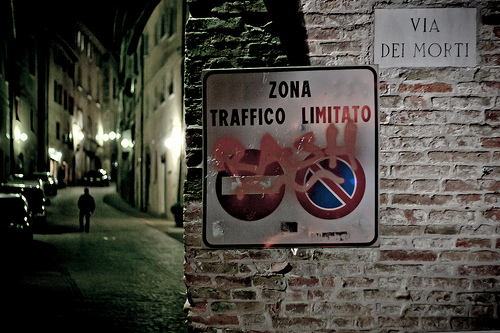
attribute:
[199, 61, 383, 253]
traffic sign — limited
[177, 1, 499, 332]
wall — made of brick, old, made of bricks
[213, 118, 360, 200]
graffiti — painted, red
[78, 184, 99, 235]
person — walking, walking at night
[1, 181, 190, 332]
street — curved, paved with bricks, narrow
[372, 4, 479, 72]
name plaque — in italian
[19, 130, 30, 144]
light — turned on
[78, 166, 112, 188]
car — black, parked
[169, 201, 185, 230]
fire hydrant — black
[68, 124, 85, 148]
light — turned on